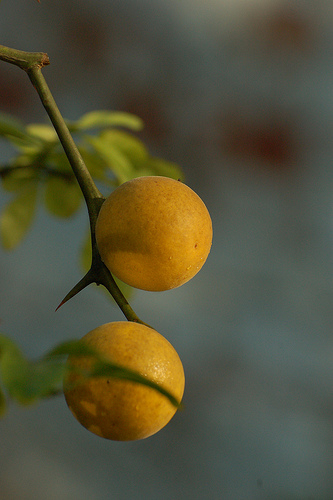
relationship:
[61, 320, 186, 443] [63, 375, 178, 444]
fruit has part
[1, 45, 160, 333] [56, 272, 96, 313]
branch has thorn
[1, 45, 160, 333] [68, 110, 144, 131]
branch has leaf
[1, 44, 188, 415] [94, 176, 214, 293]
tree has fruit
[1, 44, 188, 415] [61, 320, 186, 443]
tree has fruit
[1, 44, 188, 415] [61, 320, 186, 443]
tree has orange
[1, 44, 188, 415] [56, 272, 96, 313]
tree has thorn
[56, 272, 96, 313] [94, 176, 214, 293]
thorn next to fruit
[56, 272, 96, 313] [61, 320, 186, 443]
thorn next to fruit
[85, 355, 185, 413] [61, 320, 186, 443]
leaf in front of fruit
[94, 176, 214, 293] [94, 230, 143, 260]
fruit has shadow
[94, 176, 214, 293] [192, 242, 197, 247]
fruit has indentation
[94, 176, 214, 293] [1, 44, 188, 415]
fruit on tree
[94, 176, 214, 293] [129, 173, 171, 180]
fruit has dew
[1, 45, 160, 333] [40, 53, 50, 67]
branch has break